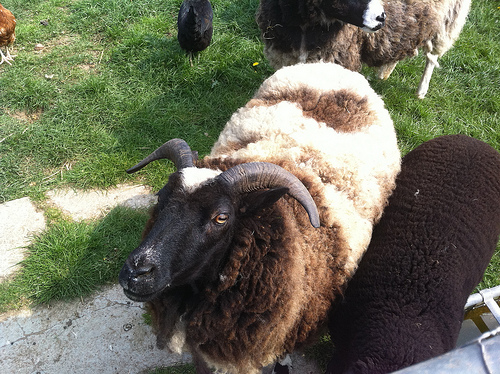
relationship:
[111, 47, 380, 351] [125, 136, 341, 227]
sheep has horns